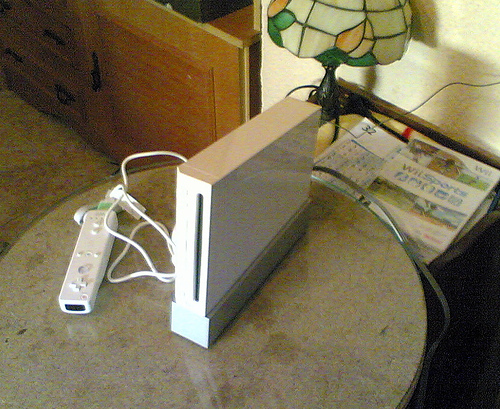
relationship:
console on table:
[170, 95, 323, 348] [331, 231, 383, 338]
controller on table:
[58, 210, 119, 315] [314, 178, 444, 406]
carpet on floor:
[0, 109, 132, 247] [2, 80, 122, 252]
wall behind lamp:
[257, 4, 499, 169] [263, 0, 413, 117]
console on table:
[170, 95, 323, 348] [0, 155, 427, 406]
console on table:
[170, 95, 323, 348] [5, 130, 440, 407]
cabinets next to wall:
[0, 0, 261, 166] [451, 22, 497, 97]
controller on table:
[58, 210, 119, 315] [5, 130, 440, 407]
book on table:
[358, 139, 500, 266] [309, 90, 497, 262]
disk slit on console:
[194, 193, 203, 302] [139, 76, 341, 346]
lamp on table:
[252, 2, 457, 129] [286, 63, 458, 243]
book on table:
[373, 118, 499, 250] [297, 107, 491, 270]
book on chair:
[312, 117, 407, 202] [273, 74, 493, 336]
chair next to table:
[273, 74, 493, 336] [0, 155, 427, 406]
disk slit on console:
[193, 194, 202, 301] [170, 95, 323, 348]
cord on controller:
[103, 150, 189, 283] [55, 207, 120, 315]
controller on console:
[55, 207, 120, 315] [170, 95, 323, 348]